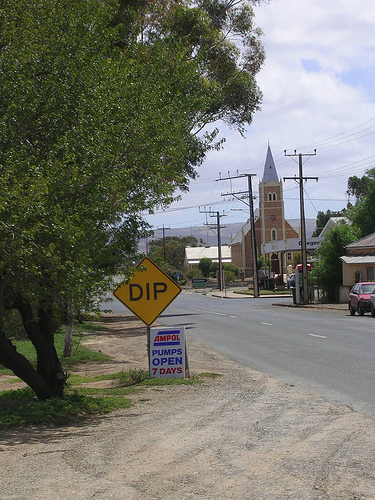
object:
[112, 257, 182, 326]
sign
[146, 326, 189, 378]
sign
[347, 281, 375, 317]
car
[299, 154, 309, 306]
pole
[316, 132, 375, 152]
cables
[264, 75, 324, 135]
air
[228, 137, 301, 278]
church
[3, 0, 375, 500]
background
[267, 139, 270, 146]
cross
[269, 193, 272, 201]
windows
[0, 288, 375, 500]
road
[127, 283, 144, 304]
letter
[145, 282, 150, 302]
letter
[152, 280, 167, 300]
letter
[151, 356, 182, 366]
word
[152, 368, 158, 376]
number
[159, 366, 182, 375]
word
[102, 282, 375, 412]
street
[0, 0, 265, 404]
tree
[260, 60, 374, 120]
clouds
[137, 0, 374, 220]
sky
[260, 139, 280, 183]
steeple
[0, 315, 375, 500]
driveway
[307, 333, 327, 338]
lines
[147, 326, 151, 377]
pole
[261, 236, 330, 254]
covering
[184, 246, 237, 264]
roof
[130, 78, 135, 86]
leaves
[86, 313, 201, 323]
shadow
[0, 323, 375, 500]
gravel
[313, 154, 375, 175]
wires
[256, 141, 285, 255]
tower